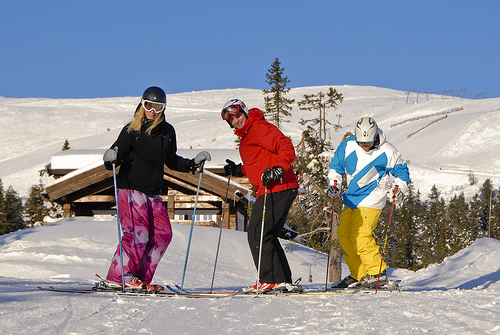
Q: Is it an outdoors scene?
A: Yes, it is outdoors.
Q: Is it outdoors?
A: Yes, it is outdoors.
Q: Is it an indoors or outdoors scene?
A: It is outdoors.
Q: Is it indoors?
A: No, it is outdoors.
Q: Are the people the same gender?
A: Yes, all the people are female.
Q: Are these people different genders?
A: No, all the people are female.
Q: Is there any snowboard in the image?
A: No, there are no snowboards.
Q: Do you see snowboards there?
A: No, there are no snowboards.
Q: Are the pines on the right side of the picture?
A: Yes, the pines are on the right of the image.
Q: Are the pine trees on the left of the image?
A: No, the pine trees are on the right of the image.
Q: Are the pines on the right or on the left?
A: The pines are on the right of the image.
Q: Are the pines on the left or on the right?
A: The pines are on the right of the image.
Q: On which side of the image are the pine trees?
A: The pine trees are on the right of the image.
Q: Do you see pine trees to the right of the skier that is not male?
A: Yes, there are pine trees to the right of the skier.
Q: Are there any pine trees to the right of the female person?
A: Yes, there are pine trees to the right of the skier.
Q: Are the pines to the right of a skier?
A: Yes, the pines are to the right of a skier.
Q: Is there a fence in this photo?
A: No, there are no fences.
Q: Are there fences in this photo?
A: No, there are no fences.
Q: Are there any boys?
A: No, there are no boys.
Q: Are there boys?
A: No, there are no boys.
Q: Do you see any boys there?
A: No, there are no boys.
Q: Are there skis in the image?
A: Yes, there are skis.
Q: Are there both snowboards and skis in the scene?
A: No, there are skis but no snowboards.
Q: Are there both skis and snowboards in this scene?
A: No, there are skis but no snowboards.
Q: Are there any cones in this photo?
A: No, there are no cones.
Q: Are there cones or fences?
A: No, there are no cones or fences.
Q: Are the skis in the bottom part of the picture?
A: Yes, the skis are in the bottom of the image.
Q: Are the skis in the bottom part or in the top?
A: The skis are in the bottom of the image.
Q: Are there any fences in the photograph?
A: No, there are no fences.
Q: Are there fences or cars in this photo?
A: No, there are no fences or cars.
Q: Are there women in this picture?
A: Yes, there is a woman.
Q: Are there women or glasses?
A: Yes, there is a woman.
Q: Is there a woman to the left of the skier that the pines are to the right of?
A: Yes, there is a woman to the left of the skier.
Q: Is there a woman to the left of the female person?
A: Yes, there is a woman to the left of the skier.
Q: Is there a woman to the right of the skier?
A: No, the woman is to the left of the skier.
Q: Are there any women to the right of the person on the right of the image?
A: No, the woman is to the left of the skier.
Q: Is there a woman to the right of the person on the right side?
A: No, the woman is to the left of the skier.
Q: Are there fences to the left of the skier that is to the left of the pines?
A: No, there is a woman to the left of the skier.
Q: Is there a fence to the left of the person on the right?
A: No, there is a woman to the left of the skier.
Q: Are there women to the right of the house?
A: Yes, there is a woman to the right of the house.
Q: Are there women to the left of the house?
A: No, the woman is to the right of the house.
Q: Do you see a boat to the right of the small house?
A: No, there is a woman to the right of the house.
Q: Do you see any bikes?
A: No, there are no bikes.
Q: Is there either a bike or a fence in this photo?
A: No, there are no bikes or fences.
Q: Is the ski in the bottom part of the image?
A: Yes, the ski is in the bottom of the image.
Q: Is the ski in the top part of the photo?
A: No, the ski is in the bottom of the image.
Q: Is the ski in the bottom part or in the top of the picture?
A: The ski is in the bottom of the image.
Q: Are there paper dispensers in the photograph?
A: No, there are no paper dispensers.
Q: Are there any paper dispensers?
A: No, there are no paper dispensers.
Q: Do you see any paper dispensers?
A: No, there are no paper dispensers.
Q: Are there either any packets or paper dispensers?
A: No, there are no paper dispensers or packets.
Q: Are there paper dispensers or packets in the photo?
A: No, there are no paper dispensers or packets.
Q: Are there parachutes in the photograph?
A: No, there are no parachutes.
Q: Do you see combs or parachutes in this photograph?
A: No, there are no parachutes or combs.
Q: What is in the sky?
A: The clouds are in the sky.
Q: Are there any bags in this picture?
A: No, there are no bags.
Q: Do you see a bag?
A: No, there are no bags.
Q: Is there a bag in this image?
A: No, there are no bags.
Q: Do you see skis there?
A: Yes, there are skis.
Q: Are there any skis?
A: Yes, there are skis.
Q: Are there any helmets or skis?
A: Yes, there are skis.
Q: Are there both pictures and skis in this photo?
A: No, there are skis but no pictures.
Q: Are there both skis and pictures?
A: No, there are skis but no pictures.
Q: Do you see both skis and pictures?
A: No, there are skis but no pictures.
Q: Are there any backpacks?
A: No, there are no backpacks.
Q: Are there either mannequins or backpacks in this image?
A: No, there are no backpacks or mannequins.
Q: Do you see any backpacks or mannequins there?
A: No, there are no backpacks or mannequins.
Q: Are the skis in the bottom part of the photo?
A: Yes, the skis are in the bottom of the image.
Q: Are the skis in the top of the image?
A: No, the skis are in the bottom of the image.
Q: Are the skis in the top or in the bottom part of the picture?
A: The skis are in the bottom of the image.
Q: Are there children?
A: No, there are no children.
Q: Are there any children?
A: No, there are no children.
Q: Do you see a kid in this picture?
A: No, there are no children.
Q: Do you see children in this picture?
A: No, there are no children.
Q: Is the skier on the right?
A: Yes, the skier is on the right of the image.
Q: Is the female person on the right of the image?
A: Yes, the skier is on the right of the image.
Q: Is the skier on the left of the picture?
A: No, the skier is on the right of the image.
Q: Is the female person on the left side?
A: No, the skier is on the right of the image.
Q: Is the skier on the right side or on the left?
A: The skier is on the right of the image.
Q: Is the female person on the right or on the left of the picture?
A: The skier is on the right of the image.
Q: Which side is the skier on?
A: The skier is on the right of the image.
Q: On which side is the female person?
A: The skier is on the right of the image.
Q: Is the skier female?
A: Yes, the skier is female.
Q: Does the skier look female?
A: Yes, the skier is female.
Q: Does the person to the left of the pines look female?
A: Yes, the skier is female.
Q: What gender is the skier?
A: The skier is female.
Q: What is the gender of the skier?
A: The skier is female.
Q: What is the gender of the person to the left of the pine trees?
A: The skier is female.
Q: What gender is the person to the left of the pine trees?
A: The skier is female.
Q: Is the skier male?
A: No, the skier is female.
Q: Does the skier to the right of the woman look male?
A: No, the skier is female.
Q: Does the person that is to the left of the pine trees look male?
A: No, the skier is female.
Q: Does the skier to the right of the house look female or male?
A: The skier is female.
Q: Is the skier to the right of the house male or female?
A: The skier is female.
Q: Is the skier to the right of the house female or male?
A: The skier is female.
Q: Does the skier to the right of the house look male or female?
A: The skier is female.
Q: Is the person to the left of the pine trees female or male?
A: The skier is female.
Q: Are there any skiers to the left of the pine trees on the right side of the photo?
A: Yes, there is a skier to the left of the pines.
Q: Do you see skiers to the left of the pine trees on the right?
A: Yes, there is a skier to the left of the pines.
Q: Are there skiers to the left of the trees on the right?
A: Yes, there is a skier to the left of the pines.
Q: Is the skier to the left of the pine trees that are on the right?
A: Yes, the skier is to the left of the pines.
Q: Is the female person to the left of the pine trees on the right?
A: Yes, the skier is to the left of the pines.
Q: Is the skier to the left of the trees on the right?
A: Yes, the skier is to the left of the pines.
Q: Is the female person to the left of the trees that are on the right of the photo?
A: Yes, the skier is to the left of the pines.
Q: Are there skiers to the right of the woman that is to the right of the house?
A: Yes, there is a skier to the right of the woman.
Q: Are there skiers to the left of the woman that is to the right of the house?
A: No, the skier is to the right of the woman.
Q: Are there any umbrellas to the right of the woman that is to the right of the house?
A: No, there is a skier to the right of the woman.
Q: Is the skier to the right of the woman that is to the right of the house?
A: Yes, the skier is to the right of the woman.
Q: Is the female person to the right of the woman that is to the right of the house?
A: Yes, the skier is to the right of the woman.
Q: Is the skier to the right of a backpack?
A: No, the skier is to the right of the woman.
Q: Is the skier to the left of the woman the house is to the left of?
A: No, the skier is to the right of the woman.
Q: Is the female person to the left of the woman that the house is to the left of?
A: No, the skier is to the right of the woman.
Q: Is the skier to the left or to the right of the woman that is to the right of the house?
A: The skier is to the right of the woman.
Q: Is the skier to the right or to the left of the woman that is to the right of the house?
A: The skier is to the right of the woman.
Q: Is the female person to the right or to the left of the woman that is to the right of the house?
A: The skier is to the right of the woman.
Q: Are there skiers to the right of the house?
A: Yes, there is a skier to the right of the house.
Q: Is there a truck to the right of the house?
A: No, there is a skier to the right of the house.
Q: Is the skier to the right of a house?
A: Yes, the skier is to the right of a house.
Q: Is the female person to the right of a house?
A: Yes, the skier is to the right of a house.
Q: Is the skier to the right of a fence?
A: No, the skier is to the right of a house.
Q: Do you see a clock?
A: No, there are no clocks.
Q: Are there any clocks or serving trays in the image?
A: No, there are no clocks or serving trays.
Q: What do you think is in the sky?
A: The clouds are in the sky.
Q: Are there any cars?
A: No, there are no cars.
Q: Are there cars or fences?
A: No, there are no cars or fences.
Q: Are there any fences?
A: No, there are no fences.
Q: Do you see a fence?
A: No, there are no fences.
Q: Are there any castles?
A: No, there are no castles.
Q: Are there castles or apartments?
A: No, there are no castles or apartments.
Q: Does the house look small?
A: Yes, the house is small.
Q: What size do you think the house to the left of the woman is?
A: The house is small.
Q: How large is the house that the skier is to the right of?
A: The house is small.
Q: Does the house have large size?
A: No, the house is small.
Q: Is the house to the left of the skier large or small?
A: The house is small.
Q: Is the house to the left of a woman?
A: Yes, the house is to the left of a woman.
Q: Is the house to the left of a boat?
A: No, the house is to the left of a woman.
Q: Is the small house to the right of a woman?
A: No, the house is to the left of a woman.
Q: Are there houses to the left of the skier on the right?
A: Yes, there is a house to the left of the skier.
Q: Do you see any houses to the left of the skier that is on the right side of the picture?
A: Yes, there is a house to the left of the skier.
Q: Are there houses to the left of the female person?
A: Yes, there is a house to the left of the skier.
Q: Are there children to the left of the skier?
A: No, there is a house to the left of the skier.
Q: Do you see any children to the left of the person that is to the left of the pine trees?
A: No, there is a house to the left of the skier.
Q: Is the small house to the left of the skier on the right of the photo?
A: Yes, the house is to the left of the skier.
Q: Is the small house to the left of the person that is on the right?
A: Yes, the house is to the left of the skier.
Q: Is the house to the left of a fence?
A: No, the house is to the left of the skier.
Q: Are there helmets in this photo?
A: Yes, there is a helmet.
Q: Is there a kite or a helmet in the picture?
A: Yes, there is a helmet.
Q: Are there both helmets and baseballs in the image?
A: No, there is a helmet but no baseballs.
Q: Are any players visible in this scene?
A: No, there are no players.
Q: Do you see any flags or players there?
A: No, there are no players or flags.